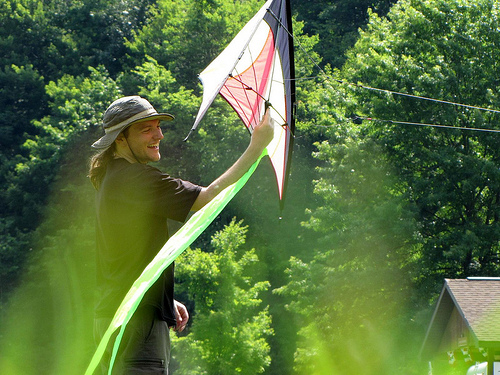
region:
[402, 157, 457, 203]
part of some tree branches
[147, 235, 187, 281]
part of a kite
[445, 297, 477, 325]
edge of a roof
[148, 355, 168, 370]
part of a zip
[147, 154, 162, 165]
chin of a man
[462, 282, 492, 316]
part of a roof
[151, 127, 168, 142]
nose of a man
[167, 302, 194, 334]
part of a hand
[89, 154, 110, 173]
hair of the man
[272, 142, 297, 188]
edge of the kite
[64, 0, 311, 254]
The man is holding a kite.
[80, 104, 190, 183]
The man is smiling.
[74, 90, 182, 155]
The man is wearing a hat.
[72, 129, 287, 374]
The kite has a tail.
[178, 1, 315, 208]
The kite is red and blue.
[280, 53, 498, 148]
Strings are attached to the kite.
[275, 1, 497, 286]
Trees are in the background.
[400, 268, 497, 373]
A building is in the background.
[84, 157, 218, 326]
The man wears a black top.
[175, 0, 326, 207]
The kite is in the air.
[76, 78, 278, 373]
a person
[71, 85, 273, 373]
the man is smiling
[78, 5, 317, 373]
a man holding a kite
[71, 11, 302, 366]
the man holds the kite with his right hand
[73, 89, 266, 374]
the man has long hair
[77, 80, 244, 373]
the man is wearing a hat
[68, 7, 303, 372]
the kite has a green tail hanging from it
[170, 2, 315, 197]
the kite is red, white and black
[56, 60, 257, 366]
the man is dressed in black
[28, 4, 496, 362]
the trees are full of green leaves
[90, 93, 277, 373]
man holding a kite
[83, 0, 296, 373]
kite is long and colorful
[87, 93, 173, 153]
hat tied to man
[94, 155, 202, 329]
black t-shirt on man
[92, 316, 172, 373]
grey pants on man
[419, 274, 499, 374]
wooden building near trees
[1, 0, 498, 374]
trees behind man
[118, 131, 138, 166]
strap on the hat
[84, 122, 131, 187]
man has long hair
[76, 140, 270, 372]
kite has a green tail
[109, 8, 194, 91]
SUNLIGHT SHINING ON GREEN LEAVES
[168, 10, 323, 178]
RED WHITE AND BLUE KITE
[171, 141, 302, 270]
GREEN TAIL ON END OF KITE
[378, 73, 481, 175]
POWER LINES RUNNING AMONGST TREES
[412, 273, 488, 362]
HOME AMONG THE TREES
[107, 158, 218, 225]
BLACK SHORT SLEEVED T-SHIRT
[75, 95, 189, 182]
MAN WITH LONG BROWN HAIR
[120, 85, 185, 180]
MAN SMILING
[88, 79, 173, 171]
MAN WEARING SUN HAT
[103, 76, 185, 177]
SUN HAT WITH CHIN STRAP